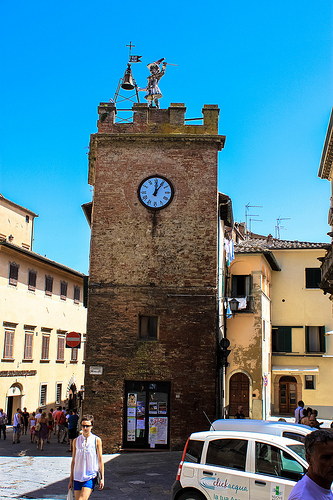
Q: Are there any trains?
A: No, there are no trains.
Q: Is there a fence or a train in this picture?
A: No, there are no trains or fences.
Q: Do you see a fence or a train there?
A: No, there are no trains or fences.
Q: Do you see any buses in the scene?
A: No, there are no buses.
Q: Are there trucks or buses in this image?
A: No, there are no buses or trucks.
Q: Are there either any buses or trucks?
A: No, there are no buses or trucks.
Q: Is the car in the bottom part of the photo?
A: Yes, the car is in the bottom of the image.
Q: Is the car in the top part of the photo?
A: No, the car is in the bottom of the image.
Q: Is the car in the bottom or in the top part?
A: The car is in the bottom of the image.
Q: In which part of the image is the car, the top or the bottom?
A: The car is in the bottom of the image.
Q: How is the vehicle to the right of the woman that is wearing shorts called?
A: The vehicle is a car.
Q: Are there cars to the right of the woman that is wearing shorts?
A: Yes, there is a car to the right of the woman.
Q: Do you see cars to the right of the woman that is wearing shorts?
A: Yes, there is a car to the right of the woman.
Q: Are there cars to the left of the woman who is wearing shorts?
A: No, the car is to the right of the woman.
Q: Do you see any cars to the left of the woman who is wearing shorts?
A: No, the car is to the right of the woman.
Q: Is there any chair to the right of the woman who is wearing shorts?
A: No, there is a car to the right of the woman.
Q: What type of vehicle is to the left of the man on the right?
A: The vehicle is a car.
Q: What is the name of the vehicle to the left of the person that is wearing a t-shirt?
A: The vehicle is a car.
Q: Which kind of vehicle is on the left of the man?
A: The vehicle is a car.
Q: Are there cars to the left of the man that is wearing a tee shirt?
A: Yes, there is a car to the left of the man.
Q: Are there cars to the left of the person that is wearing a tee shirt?
A: Yes, there is a car to the left of the man.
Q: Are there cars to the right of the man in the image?
A: No, the car is to the left of the man.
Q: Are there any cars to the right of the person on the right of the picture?
A: No, the car is to the left of the man.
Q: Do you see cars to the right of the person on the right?
A: No, the car is to the left of the man.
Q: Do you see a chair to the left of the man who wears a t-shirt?
A: No, there is a car to the left of the man.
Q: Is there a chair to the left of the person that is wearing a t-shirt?
A: No, there is a car to the left of the man.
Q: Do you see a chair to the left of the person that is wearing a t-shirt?
A: No, there is a car to the left of the man.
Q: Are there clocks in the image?
A: Yes, there is a clock.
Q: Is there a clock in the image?
A: Yes, there is a clock.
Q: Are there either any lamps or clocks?
A: Yes, there is a clock.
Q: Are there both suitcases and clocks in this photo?
A: No, there is a clock but no suitcases.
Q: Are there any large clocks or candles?
A: Yes, there is a large clock.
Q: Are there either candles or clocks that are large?
A: Yes, the clock is large.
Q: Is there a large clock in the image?
A: Yes, there is a large clock.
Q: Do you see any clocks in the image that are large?
A: Yes, there is a clock that is large.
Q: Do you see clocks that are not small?
A: Yes, there is a large clock.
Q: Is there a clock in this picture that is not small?
A: Yes, there is a large clock.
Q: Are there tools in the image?
A: No, there are no tools.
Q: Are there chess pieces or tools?
A: No, there are no tools or chess pieces.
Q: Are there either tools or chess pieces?
A: No, there are no tools or chess pieces.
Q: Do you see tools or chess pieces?
A: No, there are no tools or chess pieces.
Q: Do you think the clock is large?
A: Yes, the clock is large.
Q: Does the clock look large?
A: Yes, the clock is large.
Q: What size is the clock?
A: The clock is large.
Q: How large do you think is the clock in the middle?
A: The clock is large.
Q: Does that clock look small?
A: No, the clock is large.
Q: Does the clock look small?
A: No, the clock is large.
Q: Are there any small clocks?
A: No, there is a clock but it is large.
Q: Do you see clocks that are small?
A: No, there is a clock but it is large.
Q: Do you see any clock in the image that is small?
A: No, there is a clock but it is large.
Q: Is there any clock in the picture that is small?
A: No, there is a clock but it is large.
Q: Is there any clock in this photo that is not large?
A: No, there is a clock but it is large.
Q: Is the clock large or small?
A: The clock is large.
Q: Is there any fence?
A: No, there are no fences.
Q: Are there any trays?
A: No, there are no trays.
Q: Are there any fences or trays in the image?
A: No, there are no trays or fences.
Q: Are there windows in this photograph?
A: Yes, there is a window.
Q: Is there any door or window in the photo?
A: Yes, there is a window.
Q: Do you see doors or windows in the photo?
A: Yes, there is a window.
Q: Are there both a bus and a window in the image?
A: No, there is a window but no buses.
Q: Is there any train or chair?
A: No, there are no trains or chairs.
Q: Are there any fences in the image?
A: No, there are no fences.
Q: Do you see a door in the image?
A: Yes, there is a door.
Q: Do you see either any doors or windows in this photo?
A: Yes, there is a door.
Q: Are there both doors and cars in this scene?
A: Yes, there are both a door and a car.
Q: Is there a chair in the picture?
A: No, there are no chairs.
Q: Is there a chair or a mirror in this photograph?
A: No, there are no chairs or mirrors.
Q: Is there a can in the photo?
A: No, there are no cans.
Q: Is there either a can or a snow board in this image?
A: No, there are no cans or snowboards.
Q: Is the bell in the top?
A: Yes, the bell is in the top of the image.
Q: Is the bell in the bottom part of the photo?
A: No, the bell is in the top of the image.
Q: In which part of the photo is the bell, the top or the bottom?
A: The bell is in the top of the image.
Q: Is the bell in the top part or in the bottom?
A: The bell is in the top of the image.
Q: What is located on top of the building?
A: The bell is on top of the building.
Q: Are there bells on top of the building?
A: Yes, there is a bell on top of the building.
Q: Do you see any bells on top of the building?
A: Yes, there is a bell on top of the building.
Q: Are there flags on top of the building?
A: No, there is a bell on top of the building.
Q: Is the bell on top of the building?
A: Yes, the bell is on top of the building.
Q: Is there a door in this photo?
A: Yes, there is a door.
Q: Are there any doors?
A: Yes, there is a door.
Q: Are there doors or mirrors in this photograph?
A: Yes, there is a door.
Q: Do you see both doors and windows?
A: Yes, there are both a door and a window.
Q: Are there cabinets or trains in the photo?
A: No, there are no trains or cabinets.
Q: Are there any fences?
A: No, there are no fences.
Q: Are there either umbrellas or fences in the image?
A: No, there are no fences or umbrellas.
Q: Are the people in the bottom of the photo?
A: Yes, the people are in the bottom of the image.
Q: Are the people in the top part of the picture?
A: No, the people are in the bottom of the image.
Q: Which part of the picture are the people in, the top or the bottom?
A: The people are in the bottom of the image.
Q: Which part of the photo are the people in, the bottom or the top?
A: The people are in the bottom of the image.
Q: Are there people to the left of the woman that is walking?
A: Yes, there are people to the left of the woman.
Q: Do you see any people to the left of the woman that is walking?
A: Yes, there are people to the left of the woman.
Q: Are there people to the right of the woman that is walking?
A: No, the people are to the left of the woman.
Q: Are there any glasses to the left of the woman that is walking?
A: No, there are people to the left of the woman.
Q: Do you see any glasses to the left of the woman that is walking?
A: No, there are people to the left of the woman.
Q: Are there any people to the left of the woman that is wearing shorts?
A: Yes, there are people to the left of the woman.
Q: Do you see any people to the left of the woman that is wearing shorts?
A: Yes, there are people to the left of the woman.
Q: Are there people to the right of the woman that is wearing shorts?
A: No, the people are to the left of the woman.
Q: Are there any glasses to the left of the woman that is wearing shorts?
A: No, there are people to the left of the woman.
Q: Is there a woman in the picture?
A: Yes, there is a woman.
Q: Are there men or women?
A: Yes, there is a woman.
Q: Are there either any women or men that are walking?
A: Yes, the woman is walking.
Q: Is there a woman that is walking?
A: Yes, there is a woman that is walking.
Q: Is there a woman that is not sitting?
A: Yes, there is a woman that is walking.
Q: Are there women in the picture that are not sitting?
A: Yes, there is a woman that is walking.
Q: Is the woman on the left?
A: Yes, the woman is on the left of the image.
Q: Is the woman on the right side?
A: No, the woman is on the left of the image.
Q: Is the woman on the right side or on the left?
A: The woman is on the left of the image.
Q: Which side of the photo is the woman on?
A: The woman is on the left of the image.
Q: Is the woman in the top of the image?
A: No, the woman is in the bottom of the image.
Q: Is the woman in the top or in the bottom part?
A: The woman is in the bottom of the image.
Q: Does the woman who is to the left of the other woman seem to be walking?
A: Yes, the woman is walking.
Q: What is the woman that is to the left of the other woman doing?
A: The woman is walking.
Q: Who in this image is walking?
A: The woman is walking.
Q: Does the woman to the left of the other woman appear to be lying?
A: No, the woman is walking.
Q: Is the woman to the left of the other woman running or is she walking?
A: The woman is walking.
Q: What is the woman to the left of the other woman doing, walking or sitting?
A: The woman is walking.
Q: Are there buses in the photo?
A: No, there are no buses.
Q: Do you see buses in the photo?
A: No, there are no buses.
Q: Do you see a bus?
A: No, there are no buses.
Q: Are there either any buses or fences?
A: No, there are no buses or fences.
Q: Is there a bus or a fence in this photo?
A: No, there are no buses or fences.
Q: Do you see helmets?
A: No, there are no helmets.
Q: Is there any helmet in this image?
A: No, there are no helmets.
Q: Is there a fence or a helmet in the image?
A: No, there are no helmets or fences.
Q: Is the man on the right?
A: Yes, the man is on the right of the image.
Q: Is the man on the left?
A: No, the man is on the right of the image.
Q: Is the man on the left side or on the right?
A: The man is on the right of the image.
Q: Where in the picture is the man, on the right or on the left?
A: The man is on the right of the image.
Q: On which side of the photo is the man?
A: The man is on the right of the image.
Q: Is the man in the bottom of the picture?
A: Yes, the man is in the bottom of the image.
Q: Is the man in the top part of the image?
A: No, the man is in the bottom of the image.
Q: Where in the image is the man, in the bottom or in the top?
A: The man is in the bottom of the image.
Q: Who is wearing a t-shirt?
A: The man is wearing a t-shirt.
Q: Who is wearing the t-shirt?
A: The man is wearing a t-shirt.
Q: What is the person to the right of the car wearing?
A: The man is wearing a t-shirt.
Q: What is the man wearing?
A: The man is wearing a t-shirt.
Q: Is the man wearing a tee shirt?
A: Yes, the man is wearing a tee shirt.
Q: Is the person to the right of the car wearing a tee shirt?
A: Yes, the man is wearing a tee shirt.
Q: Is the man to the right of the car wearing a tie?
A: No, the man is wearing a tee shirt.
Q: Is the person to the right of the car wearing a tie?
A: No, the man is wearing a tee shirt.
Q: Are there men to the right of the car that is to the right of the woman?
A: Yes, there is a man to the right of the car.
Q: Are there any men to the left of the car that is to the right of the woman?
A: No, the man is to the right of the car.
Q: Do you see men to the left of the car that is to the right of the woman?
A: No, the man is to the right of the car.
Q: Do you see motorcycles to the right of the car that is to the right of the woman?
A: No, there is a man to the right of the car.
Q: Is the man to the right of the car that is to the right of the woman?
A: Yes, the man is to the right of the car.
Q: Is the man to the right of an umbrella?
A: No, the man is to the right of the car.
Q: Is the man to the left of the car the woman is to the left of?
A: No, the man is to the right of the car.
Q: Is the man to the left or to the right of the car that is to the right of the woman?
A: The man is to the right of the car.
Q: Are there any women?
A: Yes, there is a woman.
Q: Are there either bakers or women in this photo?
A: Yes, there is a woman.